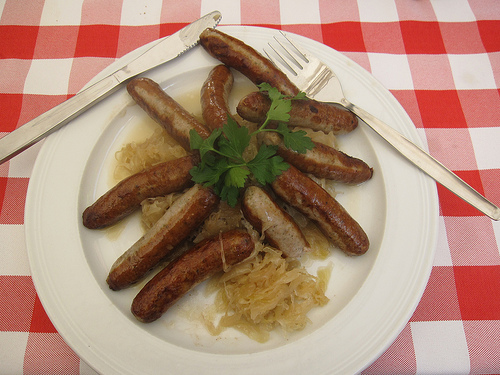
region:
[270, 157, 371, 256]
a sausage on a plate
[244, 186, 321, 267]
a sausage on a plate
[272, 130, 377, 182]
a sausage on a plate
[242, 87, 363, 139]
a sausage on a plate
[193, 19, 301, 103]
a sausage on a plate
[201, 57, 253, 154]
a sausage on a plate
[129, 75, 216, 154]
a sausage on a plate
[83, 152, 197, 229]
a sausage on a plate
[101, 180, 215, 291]
a sausage on a plate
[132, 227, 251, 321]
a sausage on a plate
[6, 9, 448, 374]
a tasty looking plate of sauerkraut and sausage links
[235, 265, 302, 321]
sauerkraut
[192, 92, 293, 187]
a sprig of parsley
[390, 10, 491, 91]
a red and white checkered tablecloth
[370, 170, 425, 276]
a shallow white bowl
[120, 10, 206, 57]
the edge of a knife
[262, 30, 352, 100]
the tines of a fork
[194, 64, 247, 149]
a sausage link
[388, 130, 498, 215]
the handle of a fork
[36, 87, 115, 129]
the handle of a knife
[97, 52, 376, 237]
Parsley on sausage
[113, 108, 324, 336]
Sausage on sauerkraut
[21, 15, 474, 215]
A fork and knife on the plate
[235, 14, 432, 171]
A four pronged fork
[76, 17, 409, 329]
Ten small sausages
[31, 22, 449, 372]
Sausage meal on a white plate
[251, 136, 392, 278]
Three browned sausages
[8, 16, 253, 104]
The knife is serrated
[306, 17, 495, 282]
Red and white plaid table cloth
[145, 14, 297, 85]
Knife and fork touch the sausage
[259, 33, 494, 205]
the fork is silver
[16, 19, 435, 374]
food on a plate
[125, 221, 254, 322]
a brown sasauge link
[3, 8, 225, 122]
the knife is silver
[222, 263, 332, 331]
the sourkraut is on plate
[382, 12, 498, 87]
the table cloth is red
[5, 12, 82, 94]
the table cloth is white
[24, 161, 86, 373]
the plate is white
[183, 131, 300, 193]
the garnish in on the food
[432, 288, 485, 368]
the table cloth is plaid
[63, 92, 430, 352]
sausage and sauerkraut on a plate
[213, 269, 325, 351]
sauerkraut on a white plate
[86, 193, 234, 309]
sausages on the white plate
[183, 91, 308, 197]
sprig of parsley is on top for decoration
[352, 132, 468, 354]
white plate is round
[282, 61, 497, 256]
fork is sitting on the edge of the white plate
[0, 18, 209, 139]
knife is sitting on the edge of the plate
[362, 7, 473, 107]
the tablecloth is red and white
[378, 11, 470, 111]
the pattern is checkered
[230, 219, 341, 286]
someone has taken a bite of this sausage